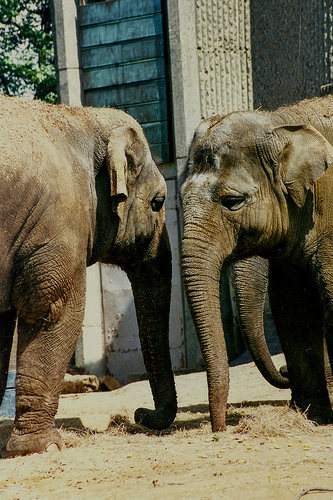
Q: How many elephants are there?
A: Two.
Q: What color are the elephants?
A: Brown.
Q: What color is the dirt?
A: Light brown.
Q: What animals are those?
A: Elephants.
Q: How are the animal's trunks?
A: Long.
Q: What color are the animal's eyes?
A: Black.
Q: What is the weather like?
A: Sunny.